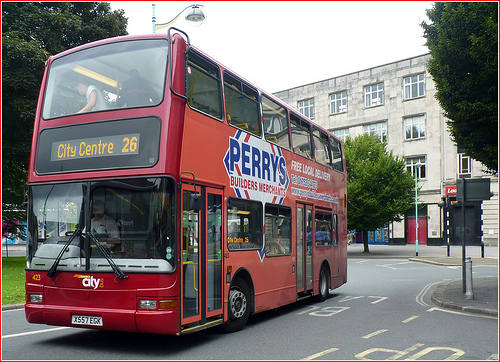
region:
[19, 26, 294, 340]
A double decker bus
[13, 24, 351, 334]
Bus is red and tall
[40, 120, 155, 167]
Sign showing bus destination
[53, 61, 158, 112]
people in bus standing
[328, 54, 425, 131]
Four story stone building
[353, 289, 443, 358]
Lines and words painted on street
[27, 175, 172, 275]
Windshield of bus is very clean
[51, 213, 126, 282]
Windshield wipes on front of bus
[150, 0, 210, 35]
Very fancy street light overhead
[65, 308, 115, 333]
Tag on front of bus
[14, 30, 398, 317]
a double decker bus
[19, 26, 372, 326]
the bus is red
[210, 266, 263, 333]
the wheel is black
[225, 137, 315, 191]
the letters are blue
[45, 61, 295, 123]
passengers on the bus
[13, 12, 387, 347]
the bus is on the street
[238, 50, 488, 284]
building behind the bus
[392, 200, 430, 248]
red door on the building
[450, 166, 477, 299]
pole on the corner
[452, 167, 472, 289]
the pole is black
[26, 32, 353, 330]
Red double decker bus on the street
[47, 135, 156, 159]
Bus number 26 going to city centre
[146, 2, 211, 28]
Street light on the pole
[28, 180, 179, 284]
Windshield and vipers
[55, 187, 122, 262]
Bus driver behind the steering wheel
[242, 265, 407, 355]
Bus lane marked on the road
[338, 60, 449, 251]
Three storied building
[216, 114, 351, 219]
Advertisement on the side of the bus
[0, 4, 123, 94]
Tall trees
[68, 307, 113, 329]
License plate in the front of the bus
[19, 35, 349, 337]
red double deck bus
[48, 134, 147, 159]
marquis sign on front of bus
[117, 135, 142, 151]
yellow number 26 on marquis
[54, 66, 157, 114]
passengers visible through bus window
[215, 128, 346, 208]
advertisement for Perrys on side of bus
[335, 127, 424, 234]
green leaves on trees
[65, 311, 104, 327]
white license plate with black letters and numbers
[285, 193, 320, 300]
side door to bus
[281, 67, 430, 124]
windows on tan building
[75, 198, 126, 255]
bus driver sitting in seat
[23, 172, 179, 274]
Lower front windshield on a double decker bus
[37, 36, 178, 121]
Upper front windshield of a double decker bus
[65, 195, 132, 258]
Bus driver inside a bus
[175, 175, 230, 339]
Front doors on a bus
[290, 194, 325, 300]
Back set of doors on a bus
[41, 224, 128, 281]
Windshield wipers on a bus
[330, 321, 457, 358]
White writing painted on the road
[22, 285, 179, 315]
Headlights on a bus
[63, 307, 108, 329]
Tag on the front of a bus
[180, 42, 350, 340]
Side of a double decker bus